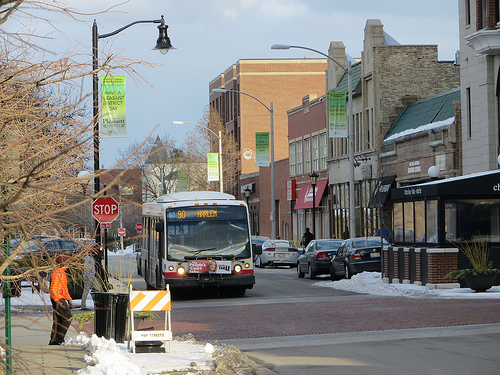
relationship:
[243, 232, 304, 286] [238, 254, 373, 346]
car parked on side of street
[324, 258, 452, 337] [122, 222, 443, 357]
snow on ground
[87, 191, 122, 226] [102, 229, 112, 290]
stop sign on pole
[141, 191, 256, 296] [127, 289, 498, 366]
bus on road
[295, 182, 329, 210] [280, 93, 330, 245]
awning on building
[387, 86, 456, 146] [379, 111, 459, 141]
roof piled with snow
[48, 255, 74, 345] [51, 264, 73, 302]
person wearing jacket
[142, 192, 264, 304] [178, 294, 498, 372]
bus coming down street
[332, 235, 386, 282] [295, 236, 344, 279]
car in back of car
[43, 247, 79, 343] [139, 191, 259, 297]
person waiting for bus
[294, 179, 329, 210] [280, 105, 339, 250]
awning of store front